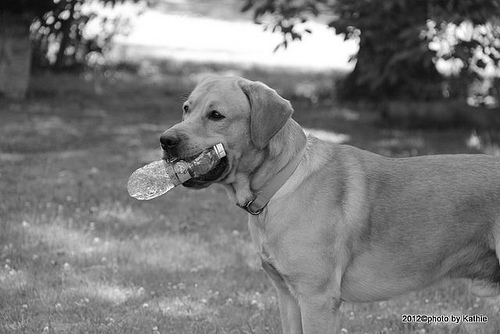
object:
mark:
[247, 297, 262, 308]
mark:
[250, 299, 259, 307]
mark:
[255, 301, 268, 309]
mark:
[250, 288, 264, 300]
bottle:
[126, 137, 227, 199]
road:
[31, 0, 498, 77]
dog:
[155, 63, 500, 334]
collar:
[238, 136, 311, 217]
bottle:
[125, 141, 230, 202]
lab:
[148, 70, 498, 332]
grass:
[1, 55, 497, 334]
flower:
[62, 259, 71, 269]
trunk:
[342, 0, 444, 97]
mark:
[138, 300, 153, 310]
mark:
[140, 301, 150, 309]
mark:
[140, 302, 151, 309]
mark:
[155, 298, 164, 305]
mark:
[133, 308, 140, 313]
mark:
[149, 323, 161, 334]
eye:
[205, 109, 227, 122]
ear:
[238, 78, 298, 150]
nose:
[153, 129, 182, 153]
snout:
[162, 137, 174, 146]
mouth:
[157, 142, 236, 196]